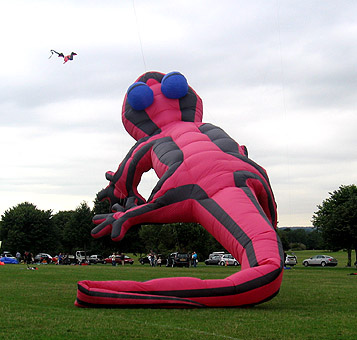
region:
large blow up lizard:
[127, 61, 301, 329]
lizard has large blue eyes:
[102, 46, 197, 113]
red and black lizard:
[104, 91, 309, 293]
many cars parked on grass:
[0, 240, 348, 280]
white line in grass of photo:
[4, 280, 232, 338]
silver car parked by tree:
[301, 173, 355, 284]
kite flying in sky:
[43, 44, 89, 69]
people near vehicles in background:
[4, 242, 94, 274]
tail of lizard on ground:
[18, 182, 248, 321]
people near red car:
[110, 250, 132, 271]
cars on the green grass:
[4, 248, 353, 269]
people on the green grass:
[1, 244, 344, 279]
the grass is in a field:
[24, 263, 105, 335]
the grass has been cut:
[10, 283, 200, 338]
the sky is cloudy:
[111, 23, 324, 82]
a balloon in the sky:
[37, 43, 100, 75]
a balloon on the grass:
[73, 55, 291, 328]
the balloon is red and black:
[77, 54, 302, 310]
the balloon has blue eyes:
[117, 69, 213, 96]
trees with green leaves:
[3, 200, 204, 256]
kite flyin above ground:
[51, 44, 115, 86]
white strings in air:
[127, 2, 319, 63]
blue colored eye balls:
[115, 67, 214, 112]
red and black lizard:
[94, 81, 289, 280]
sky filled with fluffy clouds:
[247, 52, 330, 141]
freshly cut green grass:
[61, 321, 341, 333]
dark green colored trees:
[16, 204, 116, 246]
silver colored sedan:
[308, 241, 330, 277]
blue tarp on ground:
[4, 250, 22, 268]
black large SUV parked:
[160, 248, 207, 267]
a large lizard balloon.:
[76, 50, 300, 315]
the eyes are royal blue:
[122, 78, 158, 110]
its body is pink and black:
[66, 55, 303, 311]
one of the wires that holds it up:
[125, 4, 152, 72]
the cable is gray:
[270, 4, 299, 225]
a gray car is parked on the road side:
[302, 252, 341, 268]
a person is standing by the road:
[188, 249, 198, 263]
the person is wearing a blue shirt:
[189, 249, 199, 259]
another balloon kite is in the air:
[33, 34, 86, 71]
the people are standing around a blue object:
[1, 248, 34, 264]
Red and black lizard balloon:
[67, 65, 286, 327]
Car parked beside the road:
[300, 253, 338, 269]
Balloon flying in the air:
[39, 39, 87, 67]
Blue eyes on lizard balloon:
[118, 69, 206, 113]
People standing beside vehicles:
[135, 248, 202, 267]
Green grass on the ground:
[292, 292, 345, 324]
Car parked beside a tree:
[301, 177, 356, 264]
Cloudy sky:
[264, 83, 341, 162]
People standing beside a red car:
[100, 247, 133, 268]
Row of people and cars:
[1, 246, 222, 269]